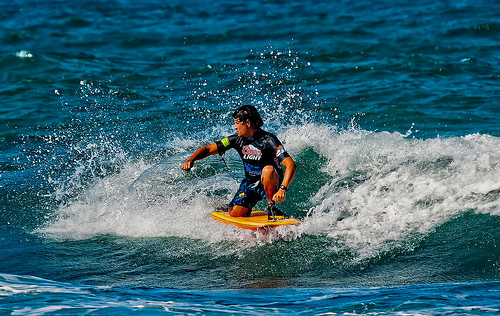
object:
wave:
[15, 117, 499, 269]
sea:
[3, 1, 497, 310]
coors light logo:
[242, 144, 262, 160]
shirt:
[215, 130, 291, 182]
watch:
[277, 184, 289, 191]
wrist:
[276, 184, 289, 192]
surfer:
[179, 103, 297, 217]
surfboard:
[210, 207, 301, 235]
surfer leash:
[213, 151, 274, 210]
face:
[233, 117, 246, 137]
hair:
[231, 104, 265, 130]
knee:
[229, 204, 247, 217]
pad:
[221, 137, 231, 147]